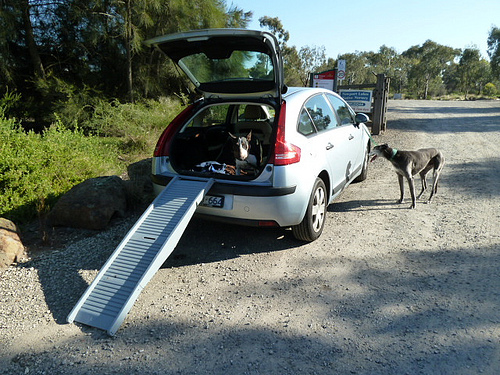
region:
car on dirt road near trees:
[56, 0, 476, 355]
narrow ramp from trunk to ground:
[65, 105, 270, 345]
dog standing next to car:
[355, 125, 455, 215]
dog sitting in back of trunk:
[210, 115, 270, 180]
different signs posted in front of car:
[305, 50, 391, 130]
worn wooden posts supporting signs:
[305, 50, 400, 135]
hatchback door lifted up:
[135, 25, 315, 107]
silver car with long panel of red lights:
[137, 72, 377, 242]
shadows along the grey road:
[350, 67, 490, 342]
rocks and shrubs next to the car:
[6, 70, 196, 243]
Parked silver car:
[130, 22, 374, 232]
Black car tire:
[296, 178, 334, 245]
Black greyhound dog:
[363, 139, 446, 217]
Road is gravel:
[213, 251, 445, 363]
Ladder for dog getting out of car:
[66, 166, 211, 338]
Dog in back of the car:
[223, 128, 267, 174]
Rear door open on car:
[135, 25, 288, 192]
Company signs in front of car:
[335, 78, 390, 119]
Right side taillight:
[274, 135, 300, 167]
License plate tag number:
[186, 190, 223, 208]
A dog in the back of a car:
[201, 123, 276, 168]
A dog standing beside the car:
[375, 132, 455, 211]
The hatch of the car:
[156, 46, 366, 103]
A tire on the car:
[297, 165, 347, 249]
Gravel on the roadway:
[16, 260, 99, 359]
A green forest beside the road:
[20, 40, 152, 171]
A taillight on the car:
[270, 98, 316, 168]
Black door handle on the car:
[319, 130, 339, 154]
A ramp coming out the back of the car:
[137, 156, 260, 275]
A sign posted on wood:
[331, 77, 411, 128]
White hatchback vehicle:
[139, 25, 374, 242]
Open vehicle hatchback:
[152, 25, 282, 175]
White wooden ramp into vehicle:
[50, 156, 222, 337]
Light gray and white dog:
[346, 138, 461, 215]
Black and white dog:
[202, 125, 269, 175]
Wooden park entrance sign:
[302, 55, 393, 142]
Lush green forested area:
[271, 32, 494, 112]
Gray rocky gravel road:
[310, 122, 485, 368]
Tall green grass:
[20, 98, 187, 234]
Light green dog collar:
[379, 145, 404, 167]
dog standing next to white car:
[364, 143, 444, 210]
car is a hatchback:
[137, 26, 375, 240]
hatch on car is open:
[147, 26, 283, 103]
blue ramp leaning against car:
[66, 174, 213, 337]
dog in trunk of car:
[225, 130, 261, 171]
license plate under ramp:
[201, 194, 224, 208]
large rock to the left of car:
[42, 174, 127, 230]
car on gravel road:
[0, 97, 498, 374]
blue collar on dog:
[389, 148, 397, 160]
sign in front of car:
[307, 60, 390, 132]